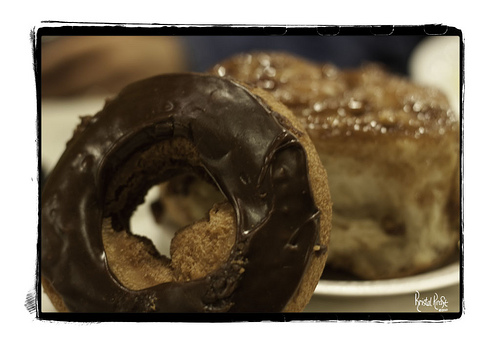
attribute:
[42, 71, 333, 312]
pastry — circular, round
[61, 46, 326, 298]
roll — cinnamon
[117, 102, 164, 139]
glazed — Chocolate 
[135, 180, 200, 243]
hole — large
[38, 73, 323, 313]
frosting — shiny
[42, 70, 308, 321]
frosting — chocolate, Brown 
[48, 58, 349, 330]
donut — round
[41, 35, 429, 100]
arm — blurry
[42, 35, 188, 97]
hand — blurry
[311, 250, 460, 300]
plate — white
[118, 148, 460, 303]
plate — white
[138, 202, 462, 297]
plate — white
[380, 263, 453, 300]
plate — white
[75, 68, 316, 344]
donut — chocolate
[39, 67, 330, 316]
donut — round, chocolate frosted, chocolate, bumpy, frosted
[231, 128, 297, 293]
frosting — sugar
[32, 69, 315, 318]
icing — chocolate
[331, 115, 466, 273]
edge — cut